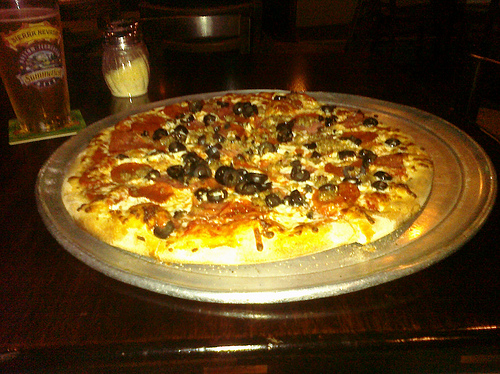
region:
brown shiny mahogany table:
[25, 320, 190, 365]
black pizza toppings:
[220, 170, 270, 190]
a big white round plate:
[260, 280, 360, 290]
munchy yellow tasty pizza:
[175, 205, 275, 260]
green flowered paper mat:
[10, 125, 55, 135]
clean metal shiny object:
[155, 20, 245, 40]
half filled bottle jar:
[5, 50, 60, 120]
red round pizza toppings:
[110, 130, 150, 145]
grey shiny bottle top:
[105, 30, 150, 40]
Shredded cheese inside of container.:
[100, 23, 160, 108]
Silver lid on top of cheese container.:
[93, 18, 170, 58]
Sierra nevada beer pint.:
[12, 19, 80, 148]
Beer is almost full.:
[25, 6, 96, 166]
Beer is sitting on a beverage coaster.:
[24, 67, 94, 144]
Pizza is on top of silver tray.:
[81, 93, 378, 338]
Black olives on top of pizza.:
[173, 147, 265, 217]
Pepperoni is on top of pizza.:
[123, 118, 234, 254]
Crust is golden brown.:
[130, 209, 268, 266]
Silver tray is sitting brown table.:
[62, 202, 185, 332]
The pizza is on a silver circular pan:
[62, 88, 474, 311]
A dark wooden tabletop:
[12, 219, 491, 351]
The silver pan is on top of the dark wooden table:
[21, 65, 488, 334]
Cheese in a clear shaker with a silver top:
[83, 17, 173, 99]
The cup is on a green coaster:
[6, 17, 108, 169]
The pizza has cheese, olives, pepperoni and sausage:
[71, 77, 446, 268]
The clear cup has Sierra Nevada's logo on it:
[0, 2, 105, 158]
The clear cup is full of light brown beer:
[4, 0, 88, 145]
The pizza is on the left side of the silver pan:
[24, 40, 475, 312]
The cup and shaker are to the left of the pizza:
[5, 2, 248, 189]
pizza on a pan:
[27, 81, 489, 310]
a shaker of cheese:
[88, 10, 158, 105]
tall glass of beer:
[0, 8, 86, 148]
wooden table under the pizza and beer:
[1, 147, 493, 364]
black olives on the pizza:
[167, 114, 306, 217]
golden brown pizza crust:
[50, 207, 300, 282]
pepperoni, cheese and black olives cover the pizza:
[73, 101, 420, 266]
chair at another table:
[138, 7, 273, 95]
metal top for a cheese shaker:
[87, 15, 152, 65]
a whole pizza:
[54, 83, 429, 270]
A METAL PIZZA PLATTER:
[27, 76, 498, 317]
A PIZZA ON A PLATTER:
[35, 75, 492, 318]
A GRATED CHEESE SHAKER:
[80, 15, 157, 102]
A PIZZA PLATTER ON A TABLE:
[20, 75, 492, 360]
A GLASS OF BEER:
[1, 1, 76, 141]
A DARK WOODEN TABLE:
[13, 265, 323, 367]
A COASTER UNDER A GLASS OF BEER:
[4, 87, 99, 149]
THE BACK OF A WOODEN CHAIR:
[134, 5, 276, 65]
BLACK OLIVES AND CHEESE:
[194, 156, 296, 216]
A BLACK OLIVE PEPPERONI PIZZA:
[60, 83, 455, 279]